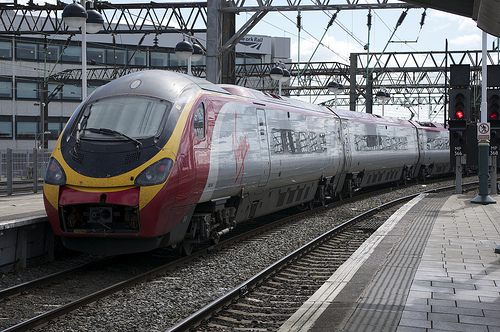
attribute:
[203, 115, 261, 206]
sign — white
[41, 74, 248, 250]
large train — stopped, long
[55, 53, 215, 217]
front — red, yellow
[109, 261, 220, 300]
ground — grey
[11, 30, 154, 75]
building — white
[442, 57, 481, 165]
light — red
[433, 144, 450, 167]
back — grey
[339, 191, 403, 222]
track — clear